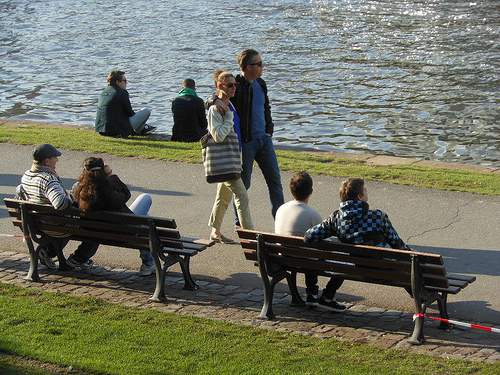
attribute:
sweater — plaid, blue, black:
[309, 208, 409, 262]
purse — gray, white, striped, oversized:
[200, 102, 242, 178]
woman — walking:
[193, 67, 258, 251]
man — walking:
[233, 50, 293, 220]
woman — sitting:
[78, 160, 161, 271]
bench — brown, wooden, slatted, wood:
[7, 201, 212, 300]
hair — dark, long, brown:
[79, 169, 110, 206]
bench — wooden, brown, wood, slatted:
[239, 231, 458, 332]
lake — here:
[1, 4, 495, 159]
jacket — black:
[102, 86, 133, 135]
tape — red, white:
[417, 308, 500, 340]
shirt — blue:
[248, 83, 265, 135]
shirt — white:
[272, 205, 324, 236]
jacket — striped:
[22, 168, 69, 233]